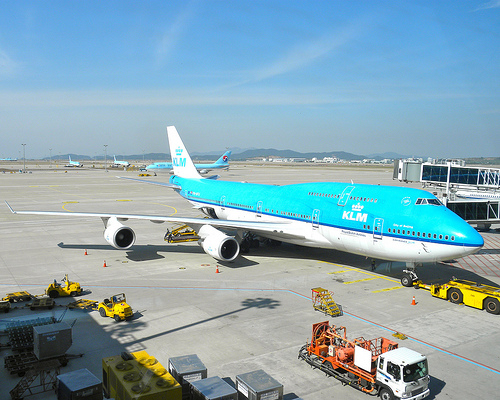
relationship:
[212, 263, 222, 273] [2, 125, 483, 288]
cone in airplane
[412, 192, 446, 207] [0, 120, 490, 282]
windows of airplane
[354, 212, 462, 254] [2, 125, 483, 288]
windows along airplane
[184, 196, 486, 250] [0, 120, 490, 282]
stripe along airplane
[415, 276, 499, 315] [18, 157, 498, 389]
carts on tarmac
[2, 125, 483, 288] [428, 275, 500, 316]
airplane towed by carts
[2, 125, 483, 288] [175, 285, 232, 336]
airplane on ground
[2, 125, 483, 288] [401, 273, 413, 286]
airplane has gear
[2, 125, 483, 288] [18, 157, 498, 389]
airplane at tarmac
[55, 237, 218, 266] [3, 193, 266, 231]
shadow of wing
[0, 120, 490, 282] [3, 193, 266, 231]
airplane has wing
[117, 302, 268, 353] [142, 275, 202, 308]
shadow on ground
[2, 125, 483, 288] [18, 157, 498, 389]
airplane on tarmac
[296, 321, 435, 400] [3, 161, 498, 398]
cab on tarmack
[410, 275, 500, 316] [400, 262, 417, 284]
luggage carrier connected to landing gear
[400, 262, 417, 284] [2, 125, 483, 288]
landing gear on airplane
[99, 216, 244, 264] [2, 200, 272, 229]
engines on wing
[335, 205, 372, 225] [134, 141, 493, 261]
lettering on background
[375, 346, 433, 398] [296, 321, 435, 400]
cab of cab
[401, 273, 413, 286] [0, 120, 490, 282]
gear of airplane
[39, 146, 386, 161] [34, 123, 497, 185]
mountain range in distance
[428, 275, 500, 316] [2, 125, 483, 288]
carts pulls airplane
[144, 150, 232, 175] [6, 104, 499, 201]
airplane in distance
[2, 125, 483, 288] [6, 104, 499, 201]
airplane in distance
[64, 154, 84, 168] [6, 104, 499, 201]
airplane in distance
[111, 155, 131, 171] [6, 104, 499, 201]
airplane in distance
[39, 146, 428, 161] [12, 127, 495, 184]
mountain range in distance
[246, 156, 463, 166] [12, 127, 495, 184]
homes in distance